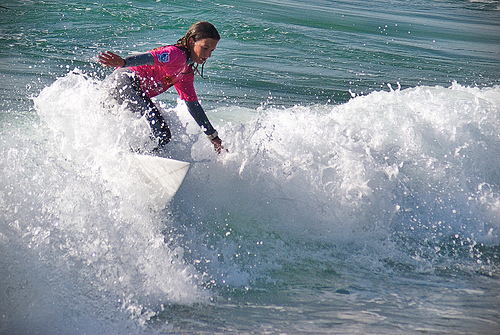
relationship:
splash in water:
[2, 65, 497, 332] [2, 0, 498, 331]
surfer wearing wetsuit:
[93, 21, 234, 161] [105, 38, 227, 161]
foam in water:
[5, 63, 498, 332] [2, 0, 498, 331]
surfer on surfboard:
[93, 21, 234, 161] [107, 153, 197, 225]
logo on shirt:
[151, 46, 180, 66] [100, 7, 230, 118]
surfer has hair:
[69, 1, 253, 202] [149, 10, 239, 48]